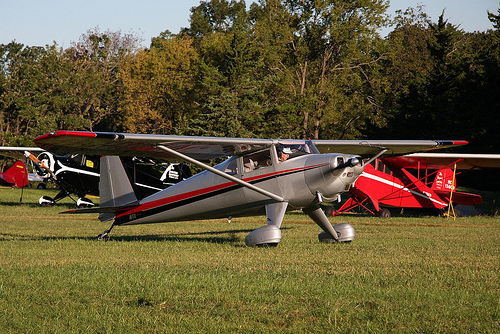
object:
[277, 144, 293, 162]
person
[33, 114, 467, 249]
gray airplane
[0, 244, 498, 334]
ground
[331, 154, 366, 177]
engine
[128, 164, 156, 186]
black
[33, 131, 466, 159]
fixed wing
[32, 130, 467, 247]
aircraft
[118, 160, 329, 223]
line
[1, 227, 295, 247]
shadow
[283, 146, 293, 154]
cap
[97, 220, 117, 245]
gear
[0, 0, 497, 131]
trees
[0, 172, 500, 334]
field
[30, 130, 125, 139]
stripes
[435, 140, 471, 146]
stripes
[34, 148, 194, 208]
black airplane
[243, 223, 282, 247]
gear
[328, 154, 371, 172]
propeller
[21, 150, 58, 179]
propeller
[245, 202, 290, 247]
landing gear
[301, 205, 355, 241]
landing gear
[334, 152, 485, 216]
airplane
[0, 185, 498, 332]
grass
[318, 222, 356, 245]
front wheel